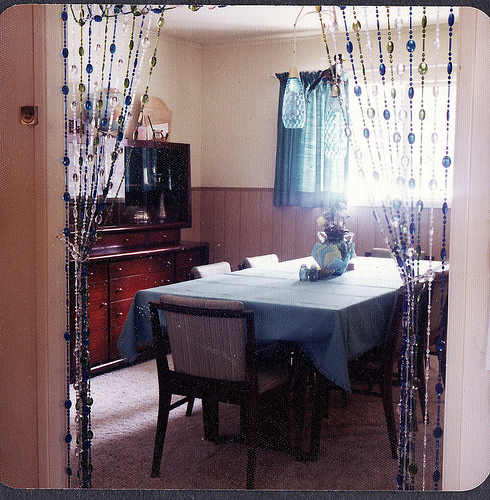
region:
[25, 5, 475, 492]
a dining room through a doorway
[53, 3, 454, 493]
hanging bead curtains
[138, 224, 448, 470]
a table in the dining room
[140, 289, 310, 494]
a chair at the end of the table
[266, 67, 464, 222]
a window behind the table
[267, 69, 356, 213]
the curtains are blue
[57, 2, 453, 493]
the beads are blue and gold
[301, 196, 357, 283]
a centerpiece on the table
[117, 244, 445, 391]
a tablecloth on the table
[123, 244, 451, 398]
the tablecloth is blue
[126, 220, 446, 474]
dining room table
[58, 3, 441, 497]
beaded curtains hanging in doorway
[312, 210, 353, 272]
vase on dining room table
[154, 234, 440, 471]
chairs tucked under dining room table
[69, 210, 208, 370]
dark wood dresser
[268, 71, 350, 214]
blue curtain on window in background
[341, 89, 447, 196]
sunlight coming through the window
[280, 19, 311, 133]
light fixture hanging from ceiling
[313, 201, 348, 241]
flowers in vase on table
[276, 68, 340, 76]
curtain rod of blue curtain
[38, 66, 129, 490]
Beading hanging over the window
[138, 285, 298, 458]
Chair sitting near the table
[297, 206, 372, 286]
Vase on top of the table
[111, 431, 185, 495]
The floor has a shadow on it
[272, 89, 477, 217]
Light shining through the window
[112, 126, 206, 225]
Tv sitting on a stand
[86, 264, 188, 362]
Drawers on the front of stand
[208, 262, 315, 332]
The tablecloth is blue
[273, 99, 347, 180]
Curtain surrounding the window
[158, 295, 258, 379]
The chair has a striped pattern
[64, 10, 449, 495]
beaded curtains in the doorway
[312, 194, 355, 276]
centerpiece on dining room table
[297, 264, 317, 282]
salt and pepper shaker on table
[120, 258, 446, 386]
blue table cloth on table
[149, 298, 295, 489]
wooden chair with striped cushions at end of table.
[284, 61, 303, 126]
crystal light fixture over table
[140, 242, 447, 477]
dining room table and six chairs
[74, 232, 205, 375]
dark wood cabinet against the wall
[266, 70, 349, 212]
blue curtain on the window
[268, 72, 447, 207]
window in dining room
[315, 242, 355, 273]
blue and white vase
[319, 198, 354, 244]
green plant in vase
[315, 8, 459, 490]
blue and gold beaded curtain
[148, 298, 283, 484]
grey and brown dining chair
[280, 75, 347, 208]
sheer blue window curtain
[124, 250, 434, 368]
blue fabric table cloth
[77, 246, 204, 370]
red wood dining hutch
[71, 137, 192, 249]
wood and glass cabinet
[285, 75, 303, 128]
glass light on ceiling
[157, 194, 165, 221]
boat figure in cabinet